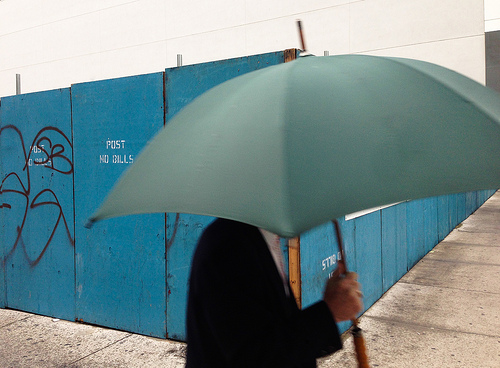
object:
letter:
[98, 153, 106, 165]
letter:
[104, 138, 112, 150]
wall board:
[69, 70, 166, 339]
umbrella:
[84, 54, 500, 241]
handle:
[351, 329, 369, 368]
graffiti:
[0, 122, 74, 269]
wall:
[1, 51, 289, 347]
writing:
[25, 156, 55, 167]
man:
[183, 218, 362, 368]